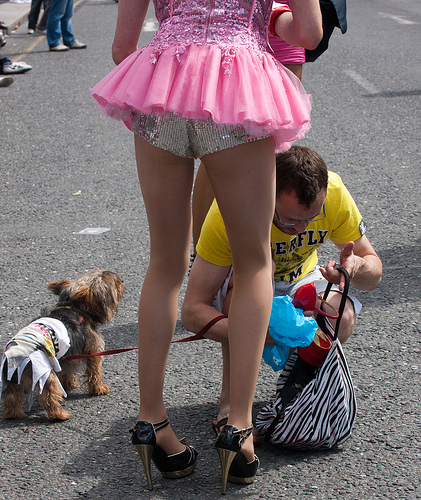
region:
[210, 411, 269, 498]
black and gold high heel shoes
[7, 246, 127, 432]
dog wearing white shirt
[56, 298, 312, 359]
rd dog leash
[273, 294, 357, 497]
black and white zebra bag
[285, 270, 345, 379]
red high heel shoe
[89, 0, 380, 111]
pink tut with sequins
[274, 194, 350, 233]
man wearing glasses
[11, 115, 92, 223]
black asphalt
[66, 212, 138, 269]
trash laying on asphalt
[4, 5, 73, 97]
yellow lines painted on asphalt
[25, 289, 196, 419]
the dog is dressed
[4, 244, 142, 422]
the dog is dressed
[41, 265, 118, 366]
the dog is dressed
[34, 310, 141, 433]
the dog is dressed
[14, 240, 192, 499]
the dog is dressed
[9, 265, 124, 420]
small brown dog wearing white outfit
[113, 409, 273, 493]
two black high heeled shoes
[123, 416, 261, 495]
black shoes with gold spiky heels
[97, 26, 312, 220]
short pink tulle skirt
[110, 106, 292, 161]
silver sequined undergarments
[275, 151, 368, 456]
man crouched looking through zebra print bag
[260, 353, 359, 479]
zebra print bag on street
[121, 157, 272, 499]
two womens legs in black high heels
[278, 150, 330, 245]
man wearing glasses looking down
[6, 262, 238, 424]
small brown dog on red leash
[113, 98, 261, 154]
shiny silver panties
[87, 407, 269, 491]
gold high heeled shoes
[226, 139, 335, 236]
a man wearing glasses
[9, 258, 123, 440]
little dog on a leash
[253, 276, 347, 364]
man holding a red shoe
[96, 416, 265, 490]
black strapped high heels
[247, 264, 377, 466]
man looking in a black and white bag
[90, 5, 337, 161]
woman wearing a pink short dress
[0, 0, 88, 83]
people standing in the street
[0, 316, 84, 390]
dog wearing the white t shirt